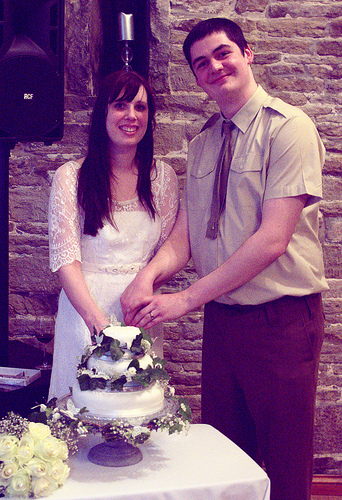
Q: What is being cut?
A: Cake.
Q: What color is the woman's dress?
A: White.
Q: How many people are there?
A: Two.